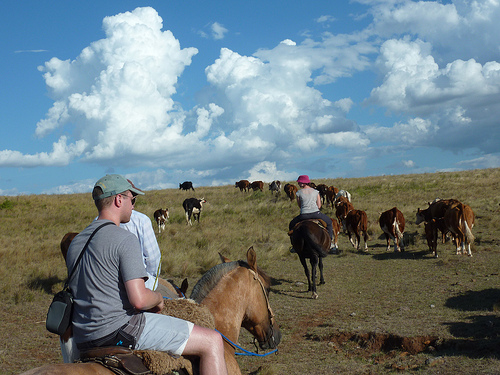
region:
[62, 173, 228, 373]
A man on a horse with a green hat and shorts.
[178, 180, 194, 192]
A black cow up on the hill near the sky.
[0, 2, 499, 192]
A blue sky with white clouds.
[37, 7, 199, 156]
The whitest puffiest cloud.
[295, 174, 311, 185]
A purple hat on a woman.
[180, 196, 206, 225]
A black and white cow.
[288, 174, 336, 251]
A woman in a purple hat and grey shirt.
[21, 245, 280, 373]
A light brown horse with blue reins.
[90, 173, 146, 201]
Dull green hat on a man's head.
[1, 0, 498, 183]
A blue sky with clouds.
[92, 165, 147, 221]
man wearing a hat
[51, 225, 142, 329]
man wearing a grey t shirt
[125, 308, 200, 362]
man wearing grey shorts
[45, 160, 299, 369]
man riding a horse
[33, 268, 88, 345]
man carrying a sachet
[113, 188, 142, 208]
man wearing sunglasses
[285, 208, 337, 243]
woman wearing blue jeans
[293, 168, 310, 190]
woman wearing a red hat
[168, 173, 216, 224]
cows in a field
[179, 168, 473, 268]
group of cows being herded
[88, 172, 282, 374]
a man riding a horse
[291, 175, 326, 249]
a woman riding a horse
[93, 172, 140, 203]
a man wearing a green hat